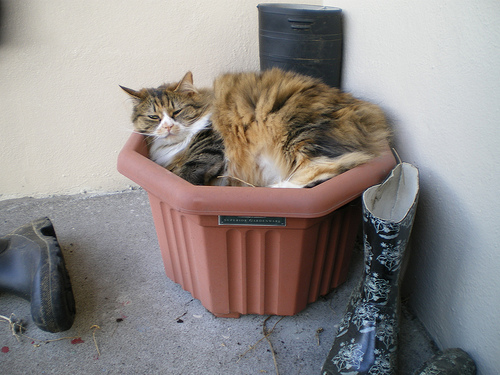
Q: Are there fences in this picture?
A: No, there are no fences.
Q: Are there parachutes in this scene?
A: No, there are no parachutes.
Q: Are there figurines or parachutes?
A: No, there are no parachutes or figurines.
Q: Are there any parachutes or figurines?
A: No, there are no parachutes or figurines.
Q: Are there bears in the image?
A: No, there are no bears.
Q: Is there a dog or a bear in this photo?
A: No, there are no bears or dogs.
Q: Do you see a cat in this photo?
A: Yes, there is a cat.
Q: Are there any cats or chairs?
A: Yes, there is a cat.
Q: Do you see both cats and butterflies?
A: No, there is a cat but no butterflies.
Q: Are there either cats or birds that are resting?
A: Yes, the cat is resting.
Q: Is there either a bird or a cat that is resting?
A: Yes, the cat is resting.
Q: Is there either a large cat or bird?
A: Yes, there is a large cat.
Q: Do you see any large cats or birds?
A: Yes, there is a large cat.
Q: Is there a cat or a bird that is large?
A: Yes, the cat is large.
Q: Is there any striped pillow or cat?
A: Yes, there is a striped cat.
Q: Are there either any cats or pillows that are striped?
A: Yes, the cat is striped.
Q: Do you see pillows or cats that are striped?
A: Yes, the cat is striped.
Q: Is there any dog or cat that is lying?
A: Yes, the cat is lying.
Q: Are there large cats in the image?
A: Yes, there is a large cat.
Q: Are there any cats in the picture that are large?
A: Yes, there is a cat that is large.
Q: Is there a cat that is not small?
A: Yes, there is a large cat.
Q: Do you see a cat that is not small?
A: Yes, there is a large cat.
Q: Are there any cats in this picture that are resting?
A: Yes, there is a cat that is resting.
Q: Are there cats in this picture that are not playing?
A: Yes, there is a cat that is resting.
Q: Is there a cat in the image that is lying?
A: Yes, there is a cat that is lying.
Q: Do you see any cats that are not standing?
A: Yes, there is a cat that is lying .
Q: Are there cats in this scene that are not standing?
A: Yes, there is a cat that is lying.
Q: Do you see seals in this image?
A: No, there are no seals.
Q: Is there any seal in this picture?
A: No, there are no seals.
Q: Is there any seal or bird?
A: No, there are no seals or birds.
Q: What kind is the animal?
A: The animal is a cat.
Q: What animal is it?
A: The animal is a cat.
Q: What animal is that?
A: This is a cat.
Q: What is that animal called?
A: This is a cat.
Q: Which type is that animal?
A: This is a cat.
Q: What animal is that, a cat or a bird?
A: This is a cat.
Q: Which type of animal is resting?
A: The animal is a cat.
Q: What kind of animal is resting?
A: The animal is a cat.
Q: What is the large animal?
A: The animal is a cat.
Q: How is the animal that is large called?
A: The animal is a cat.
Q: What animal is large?
A: The animal is a cat.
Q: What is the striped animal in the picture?
A: The animal is a cat.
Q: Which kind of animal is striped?
A: The animal is a cat.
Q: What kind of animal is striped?
A: The animal is a cat.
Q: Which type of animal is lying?
A: The animal is a cat.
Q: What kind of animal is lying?
A: The animal is a cat.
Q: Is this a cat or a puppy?
A: This is a cat.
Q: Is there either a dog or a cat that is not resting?
A: No, there is a cat but it is resting.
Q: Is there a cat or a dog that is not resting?
A: No, there is a cat but it is resting.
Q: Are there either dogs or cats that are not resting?
A: No, there is a cat but it is resting.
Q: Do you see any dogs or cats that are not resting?
A: No, there is a cat but it is resting.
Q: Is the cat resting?
A: Yes, the cat is resting.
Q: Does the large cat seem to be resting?
A: Yes, the cat is resting.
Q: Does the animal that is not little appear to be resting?
A: Yes, the cat is resting.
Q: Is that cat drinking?
A: No, the cat is resting.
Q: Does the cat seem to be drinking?
A: No, the cat is resting.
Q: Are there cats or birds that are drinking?
A: No, there is a cat but it is resting.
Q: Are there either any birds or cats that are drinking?
A: No, there is a cat but it is resting.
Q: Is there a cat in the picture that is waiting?
A: No, there is a cat but it is resting.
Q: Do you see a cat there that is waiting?
A: No, there is a cat but it is resting.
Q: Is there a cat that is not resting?
A: No, there is a cat but it is resting.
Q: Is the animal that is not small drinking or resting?
A: The cat is resting.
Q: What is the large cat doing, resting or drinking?
A: The cat is resting.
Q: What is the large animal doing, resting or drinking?
A: The cat is resting.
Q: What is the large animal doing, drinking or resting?
A: The cat is resting.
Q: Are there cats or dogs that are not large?
A: No, there is a cat but it is large.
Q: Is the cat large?
A: Yes, the cat is large.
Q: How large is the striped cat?
A: The cat is large.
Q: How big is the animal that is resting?
A: The cat is large.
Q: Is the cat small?
A: No, the cat is large.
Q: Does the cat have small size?
A: No, the cat is large.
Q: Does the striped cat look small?
A: No, the cat is large.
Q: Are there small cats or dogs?
A: No, there is a cat but it is large.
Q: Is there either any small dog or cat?
A: No, there is a cat but it is large.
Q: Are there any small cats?
A: No, there is a cat but it is large.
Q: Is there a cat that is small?
A: No, there is a cat but it is large.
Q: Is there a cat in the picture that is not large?
A: No, there is a cat but it is large.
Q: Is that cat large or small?
A: The cat is large.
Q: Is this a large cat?
A: Yes, this is a large cat.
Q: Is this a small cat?
A: No, this is a large cat.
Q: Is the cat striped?
A: Yes, the cat is striped.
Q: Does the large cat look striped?
A: Yes, the cat is striped.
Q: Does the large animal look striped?
A: Yes, the cat is striped.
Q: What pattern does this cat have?
A: The cat has striped pattern.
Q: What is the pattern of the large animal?
A: The cat is striped.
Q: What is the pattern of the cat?
A: The cat is striped.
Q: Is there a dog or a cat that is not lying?
A: No, there is a cat but it is lying.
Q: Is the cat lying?
A: Yes, the cat is lying.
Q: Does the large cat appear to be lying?
A: Yes, the cat is lying.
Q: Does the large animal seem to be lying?
A: Yes, the cat is lying.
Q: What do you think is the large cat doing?
A: The cat is lying.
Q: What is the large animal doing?
A: The cat is lying.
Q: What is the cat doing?
A: The cat is lying.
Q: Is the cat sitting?
A: No, the cat is lying.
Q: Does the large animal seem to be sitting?
A: No, the cat is lying.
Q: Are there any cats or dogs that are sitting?
A: No, there is a cat but it is lying.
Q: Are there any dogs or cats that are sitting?
A: No, there is a cat but it is lying.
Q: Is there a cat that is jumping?
A: No, there is a cat but it is lying.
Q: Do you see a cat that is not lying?
A: No, there is a cat but it is lying.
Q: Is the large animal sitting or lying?
A: The cat is lying.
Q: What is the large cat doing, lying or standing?
A: The cat is lying.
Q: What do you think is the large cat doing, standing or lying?
A: The cat is lying.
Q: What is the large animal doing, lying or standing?
A: The cat is lying.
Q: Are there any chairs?
A: No, there are no chairs.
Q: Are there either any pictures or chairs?
A: No, there are no chairs or pictures.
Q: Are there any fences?
A: No, there are no fences.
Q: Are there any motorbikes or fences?
A: No, there are no fences or motorbikes.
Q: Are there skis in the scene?
A: No, there are no skis.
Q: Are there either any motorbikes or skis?
A: No, there are no skis or motorbikes.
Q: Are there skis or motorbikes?
A: No, there are no skis or motorbikes.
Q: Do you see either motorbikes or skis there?
A: No, there are no skis or motorbikes.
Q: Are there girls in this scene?
A: No, there are no girls.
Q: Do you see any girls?
A: No, there are no girls.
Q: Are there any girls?
A: No, there are no girls.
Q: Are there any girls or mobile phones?
A: No, there are no girls or mobile phones.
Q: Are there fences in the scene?
A: No, there are no fences.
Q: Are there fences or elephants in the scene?
A: No, there are no fences or elephants.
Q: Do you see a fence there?
A: No, there are no fences.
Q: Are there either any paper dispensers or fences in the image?
A: No, there are no fences or paper dispensers.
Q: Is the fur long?
A: Yes, the fur is long.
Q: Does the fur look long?
A: Yes, the fur is long.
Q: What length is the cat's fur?
A: The fur is long.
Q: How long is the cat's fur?
A: The fur is long.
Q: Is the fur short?
A: No, the fur is long.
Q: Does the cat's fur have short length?
A: No, the fur is long.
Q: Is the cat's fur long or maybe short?
A: The fur is long.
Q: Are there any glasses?
A: No, there are no glasses.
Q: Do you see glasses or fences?
A: No, there are no glasses or fences.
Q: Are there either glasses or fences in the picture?
A: No, there are no glasses or fences.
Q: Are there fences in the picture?
A: No, there are no fences.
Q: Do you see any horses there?
A: No, there are no horses.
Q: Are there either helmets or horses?
A: No, there are no horses or helmets.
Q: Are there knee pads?
A: No, there are no knee pads.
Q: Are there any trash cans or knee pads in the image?
A: No, there are no knee pads or trash cans.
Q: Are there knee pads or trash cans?
A: No, there are no knee pads or trash cans.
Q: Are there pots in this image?
A: Yes, there is a pot.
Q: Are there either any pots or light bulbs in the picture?
A: Yes, there is a pot.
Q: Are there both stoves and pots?
A: No, there is a pot but no stoves.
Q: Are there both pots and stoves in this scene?
A: No, there is a pot but no stoves.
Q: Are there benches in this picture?
A: No, there are no benches.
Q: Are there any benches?
A: No, there are no benches.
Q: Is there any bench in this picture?
A: No, there are no benches.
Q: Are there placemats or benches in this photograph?
A: No, there are no benches or placemats.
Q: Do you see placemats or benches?
A: No, there are no benches or placemats.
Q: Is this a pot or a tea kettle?
A: This is a pot.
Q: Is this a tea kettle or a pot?
A: This is a pot.